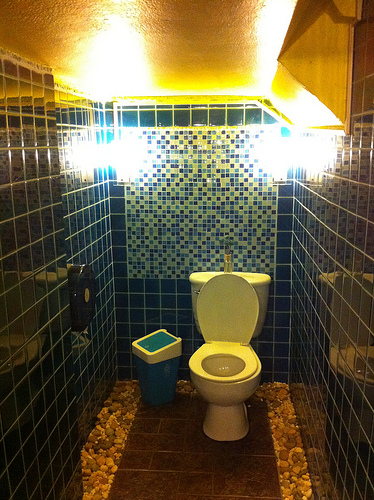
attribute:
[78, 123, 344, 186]
lights — on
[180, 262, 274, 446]
toilet — white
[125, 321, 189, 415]
trash can — blue, white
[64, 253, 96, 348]
dispenser — black, round, gray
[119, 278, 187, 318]
tile — blue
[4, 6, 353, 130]
ceiling — yellow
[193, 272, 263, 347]
lid — white, up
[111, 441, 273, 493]
tile — brown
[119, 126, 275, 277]
tiles — blue, white, checkered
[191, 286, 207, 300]
handle — silver